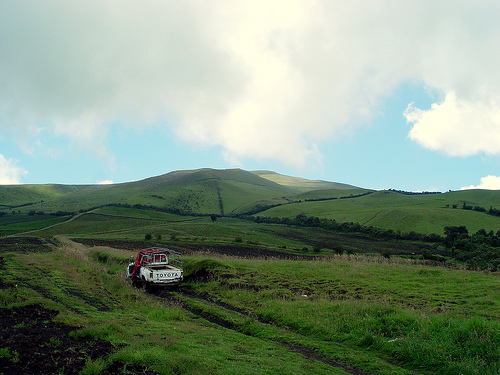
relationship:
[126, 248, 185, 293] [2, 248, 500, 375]
truck in field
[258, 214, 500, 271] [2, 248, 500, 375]
trees in field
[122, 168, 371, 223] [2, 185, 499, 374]
mountain in field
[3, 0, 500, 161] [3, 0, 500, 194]
clouds in sky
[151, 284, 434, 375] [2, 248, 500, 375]
tracks on field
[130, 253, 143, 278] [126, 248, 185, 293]
door on truck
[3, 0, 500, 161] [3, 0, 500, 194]
clouds are in sky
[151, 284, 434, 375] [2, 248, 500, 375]
tracks in field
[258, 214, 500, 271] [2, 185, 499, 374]
trees are in field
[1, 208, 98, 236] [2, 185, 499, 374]
road in field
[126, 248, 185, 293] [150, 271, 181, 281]
truck has tailgate